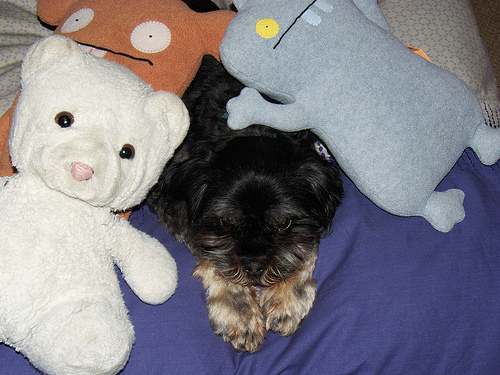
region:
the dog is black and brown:
[178, 146, 413, 373]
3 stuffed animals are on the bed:
[13, 5, 482, 248]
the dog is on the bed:
[159, 123, 478, 364]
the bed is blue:
[332, 181, 491, 357]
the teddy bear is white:
[8, 54, 260, 366]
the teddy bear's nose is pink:
[52, 159, 161, 233]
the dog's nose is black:
[236, 255, 292, 292]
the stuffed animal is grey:
[226, 3, 497, 220]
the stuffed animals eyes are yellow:
[242, 16, 327, 80]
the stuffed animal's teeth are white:
[287, 5, 452, 60]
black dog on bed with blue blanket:
[107, 60, 411, 372]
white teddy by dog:
[25, 32, 357, 354]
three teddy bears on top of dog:
[17, 8, 428, 338]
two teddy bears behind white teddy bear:
[32, 12, 430, 172]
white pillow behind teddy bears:
[217, 2, 491, 84]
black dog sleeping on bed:
[118, 102, 418, 362]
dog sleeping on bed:
[32, 27, 432, 287]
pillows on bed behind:
[4, 4, 299, 146]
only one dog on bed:
[117, 84, 362, 374]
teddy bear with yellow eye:
[220, 11, 434, 81]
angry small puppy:
[170, 156, 347, 328]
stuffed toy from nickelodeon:
[247, 2, 484, 205]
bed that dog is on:
[342, 224, 456, 323]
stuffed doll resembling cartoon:
[70, 4, 189, 66]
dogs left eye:
[255, 195, 295, 245]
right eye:
[203, 180, 227, 239]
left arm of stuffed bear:
[114, 227, 206, 312]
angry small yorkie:
[190, 170, 385, 305]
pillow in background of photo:
[387, 2, 481, 37]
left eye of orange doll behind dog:
[126, 8, 187, 71]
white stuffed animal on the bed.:
[32, 88, 141, 245]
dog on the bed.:
[202, 156, 317, 316]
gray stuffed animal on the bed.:
[302, 23, 415, 148]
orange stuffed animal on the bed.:
[84, 19, 193, 41]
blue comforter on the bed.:
[360, 257, 445, 344]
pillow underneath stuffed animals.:
[416, 7, 463, 45]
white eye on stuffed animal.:
[132, 23, 169, 50]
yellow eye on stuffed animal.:
[257, 19, 278, 36]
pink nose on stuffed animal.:
[71, 162, 96, 179]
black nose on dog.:
[233, 261, 266, 283]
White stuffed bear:
[0, 40, 187, 372]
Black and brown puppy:
[163, 143, 350, 348]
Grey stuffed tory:
[230, 0, 494, 128]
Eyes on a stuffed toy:
[47, 3, 229, 49]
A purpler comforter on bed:
[312, 242, 494, 373]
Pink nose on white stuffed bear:
[52, 155, 116, 195]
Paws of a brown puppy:
[199, 277, 335, 357]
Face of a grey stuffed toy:
[240, 0, 362, 78]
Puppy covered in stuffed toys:
[15, 3, 447, 350]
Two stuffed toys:
[2, 0, 193, 374]